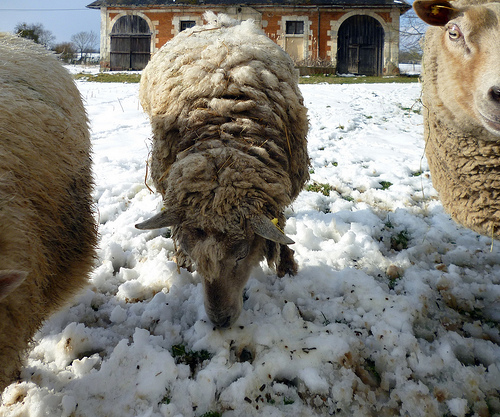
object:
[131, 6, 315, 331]
sheep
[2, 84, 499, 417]
snow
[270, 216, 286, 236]
ear tag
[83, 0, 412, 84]
building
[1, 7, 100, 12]
power line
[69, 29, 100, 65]
tree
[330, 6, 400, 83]
doorway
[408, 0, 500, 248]
sheep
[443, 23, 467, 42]
eye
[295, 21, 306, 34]
window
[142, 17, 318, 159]
back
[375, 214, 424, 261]
sheep tracks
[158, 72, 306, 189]
fur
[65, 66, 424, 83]
grass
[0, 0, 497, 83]
back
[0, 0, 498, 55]
sky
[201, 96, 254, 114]
wool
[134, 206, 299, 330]
head